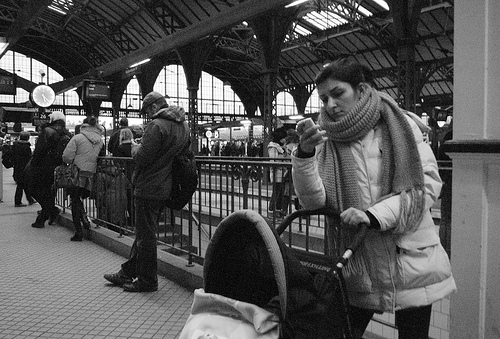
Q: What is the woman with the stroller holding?
A: A phone.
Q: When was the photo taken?
A: Day time.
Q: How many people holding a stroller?
A: One.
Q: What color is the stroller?
A: Black.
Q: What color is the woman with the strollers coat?
A: White.